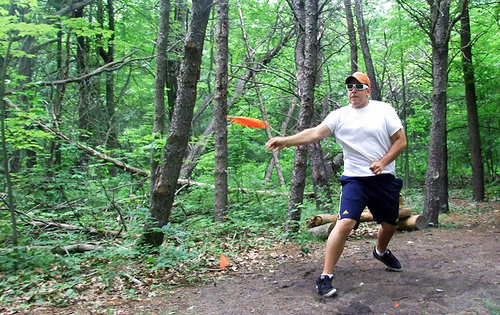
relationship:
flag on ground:
[216, 252, 236, 269] [54, 206, 498, 315]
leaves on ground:
[242, 243, 268, 268] [54, 206, 498, 315]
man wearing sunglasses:
[288, 62, 419, 278] [347, 84, 372, 91]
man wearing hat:
[288, 62, 419, 278] [347, 72, 369, 90]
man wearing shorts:
[288, 62, 419, 278] [338, 179, 397, 227]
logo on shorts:
[341, 209, 350, 217] [338, 179, 397, 227]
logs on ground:
[314, 204, 423, 234] [54, 206, 498, 315]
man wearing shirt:
[288, 62, 419, 278] [324, 99, 402, 180]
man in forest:
[288, 62, 419, 278] [2, 5, 499, 315]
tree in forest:
[152, 6, 189, 254] [2, 5, 499, 315]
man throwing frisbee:
[288, 62, 419, 278] [229, 109, 263, 130]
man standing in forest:
[288, 62, 419, 278] [2, 5, 499, 315]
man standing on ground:
[288, 62, 419, 278] [54, 206, 498, 315]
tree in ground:
[152, 6, 189, 254] [54, 206, 498, 315]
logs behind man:
[314, 204, 423, 234] [288, 62, 419, 278]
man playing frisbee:
[288, 62, 419, 278] [229, 109, 263, 130]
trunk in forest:
[175, 20, 193, 175] [2, 5, 499, 315]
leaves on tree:
[242, 243, 268, 268] [152, 6, 189, 254]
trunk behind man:
[175, 20, 193, 175] [288, 62, 419, 278]